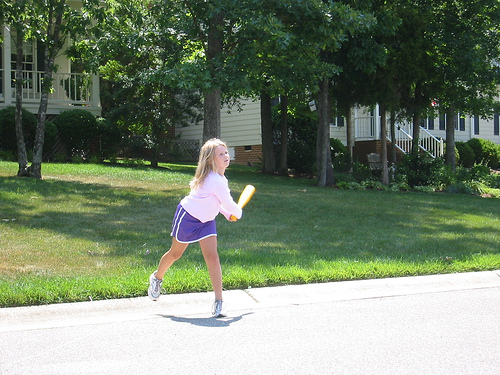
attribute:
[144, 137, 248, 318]
girl — standing, playing, little, young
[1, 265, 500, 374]
street — concrete, paved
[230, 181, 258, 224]
bat — yellow, baseball, plastic, plsatic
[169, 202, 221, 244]
shorts — white, blue, purple, athletic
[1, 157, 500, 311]
lawn — green, grassy, beautiful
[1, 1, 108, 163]
houses — white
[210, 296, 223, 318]
sneakers — white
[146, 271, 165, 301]
sneakers — white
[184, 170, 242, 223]
jacket — white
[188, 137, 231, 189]
hair — blonde, long, blond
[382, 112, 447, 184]
steps — white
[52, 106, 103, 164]
shrubs — green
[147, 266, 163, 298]
foot — raised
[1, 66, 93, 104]
railing — white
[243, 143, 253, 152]
window — rectangle